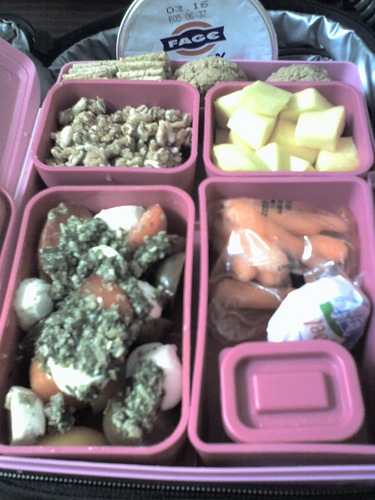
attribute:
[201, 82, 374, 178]
container — square, purple, plastic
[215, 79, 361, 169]
cheese — white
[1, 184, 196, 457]
container — rectangular, purple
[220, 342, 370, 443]
container — small, covered, purple, plastic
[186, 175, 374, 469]
container — purple, plastic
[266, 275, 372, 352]
cheese — wrapped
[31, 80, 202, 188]
container — purple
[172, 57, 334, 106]
cookies — brown, stacked, oatmeal, for dessert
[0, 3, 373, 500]
cooler — silver, fabric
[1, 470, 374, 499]
zipper — silver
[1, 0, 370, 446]
lunch — delicious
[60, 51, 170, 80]
crackers — saltine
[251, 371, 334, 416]
shape — square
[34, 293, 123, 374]
pesto — green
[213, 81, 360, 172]
apples — diced, white, golden delicious, sliced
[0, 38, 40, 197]
lid — pink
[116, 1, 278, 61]
yogurt — fage, greek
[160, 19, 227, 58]
label — black, red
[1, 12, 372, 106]
edge — silver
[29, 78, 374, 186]
containers — small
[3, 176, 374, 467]
containers — large